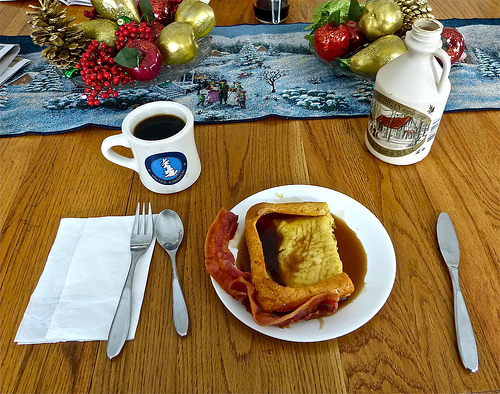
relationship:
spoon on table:
[154, 209, 188, 336] [237, 127, 342, 183]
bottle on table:
[380, 34, 453, 172] [8, 43, 475, 378]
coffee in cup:
[127, 115, 185, 140] [101, 101, 201, 194]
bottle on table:
[364, 19, 451, 165] [2, 1, 499, 392]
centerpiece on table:
[33, 10, 229, 100] [2, 1, 499, 392]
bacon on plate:
[204, 202, 354, 329] [186, 171, 398, 351]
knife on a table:
[434, 230, 464, 316] [2, 1, 499, 392]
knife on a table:
[436, 211, 478, 374] [340, 339, 419, 394]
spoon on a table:
[152, 207, 191, 335] [16, 134, 494, 384]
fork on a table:
[103, 199, 153, 359] [2, 1, 499, 392]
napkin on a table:
[13, 214, 156, 345] [2, 1, 499, 392]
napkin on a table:
[32, 209, 157, 346] [16, 134, 494, 384]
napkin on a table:
[19, 213, 154, 346] [2, 1, 499, 392]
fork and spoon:
[103, 199, 153, 359] [151, 206, 202, 337]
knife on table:
[436, 211, 478, 374] [2, 1, 499, 392]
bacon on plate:
[193, 200, 339, 332] [197, 178, 411, 349]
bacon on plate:
[204, 202, 354, 329] [321, 271, 351, 353]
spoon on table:
[154, 209, 188, 336] [192, 331, 203, 394]